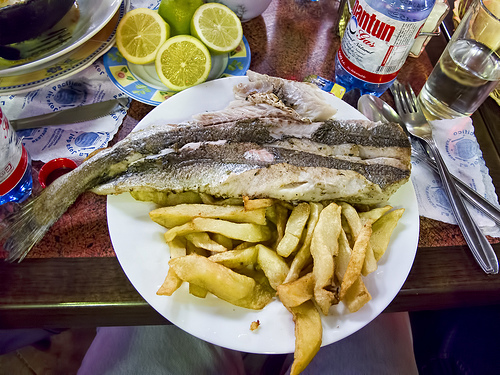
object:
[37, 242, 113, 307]
table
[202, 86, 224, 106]
plate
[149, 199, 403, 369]
french fries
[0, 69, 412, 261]
fish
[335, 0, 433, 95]
bottle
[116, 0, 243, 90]
fruit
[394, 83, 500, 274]
fork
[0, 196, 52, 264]
tail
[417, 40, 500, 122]
liquid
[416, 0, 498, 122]
glass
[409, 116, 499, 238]
napkin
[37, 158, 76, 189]
cap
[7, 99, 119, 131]
knife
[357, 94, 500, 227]
spoon